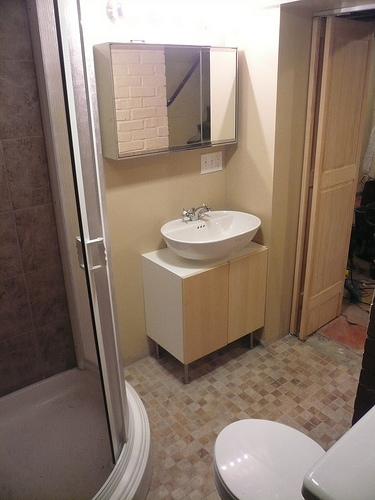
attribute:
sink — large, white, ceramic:
[157, 205, 261, 266]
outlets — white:
[199, 143, 227, 175]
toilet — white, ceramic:
[206, 396, 373, 497]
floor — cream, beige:
[126, 317, 360, 499]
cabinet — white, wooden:
[143, 233, 272, 369]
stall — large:
[3, 0, 159, 497]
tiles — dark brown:
[0, 4, 81, 394]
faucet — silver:
[177, 200, 210, 223]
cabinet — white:
[139, 240, 271, 366]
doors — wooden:
[188, 249, 270, 362]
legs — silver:
[152, 328, 257, 385]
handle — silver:
[179, 200, 214, 226]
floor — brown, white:
[173, 380, 273, 416]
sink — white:
[141, 190, 290, 304]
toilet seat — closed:
[165, 366, 365, 498]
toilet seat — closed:
[210, 364, 349, 496]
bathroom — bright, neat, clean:
[3, 2, 373, 494]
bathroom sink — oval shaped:
[143, 153, 288, 316]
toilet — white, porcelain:
[153, 317, 372, 498]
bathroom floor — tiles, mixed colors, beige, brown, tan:
[188, 340, 370, 413]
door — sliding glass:
[1, 2, 109, 488]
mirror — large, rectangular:
[86, 29, 251, 185]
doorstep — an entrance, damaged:
[286, 254, 373, 369]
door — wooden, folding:
[268, 8, 372, 372]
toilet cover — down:
[182, 357, 347, 498]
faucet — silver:
[168, 186, 236, 231]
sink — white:
[143, 192, 281, 284]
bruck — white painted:
[96, 40, 179, 168]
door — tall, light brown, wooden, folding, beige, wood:
[288, 14, 373, 342]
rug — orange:
[318, 300, 371, 355]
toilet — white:
[214, 402, 371, 498]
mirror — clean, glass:
[163, 43, 210, 149]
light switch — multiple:
[199, 151, 222, 172]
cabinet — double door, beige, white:
[141, 242, 268, 383]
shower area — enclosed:
[2, 0, 155, 497]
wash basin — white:
[161, 209, 261, 264]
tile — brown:
[181, 394, 193, 404]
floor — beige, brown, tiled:
[120, 334, 364, 497]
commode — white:
[208, 418, 324, 498]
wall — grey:
[0, 0, 81, 396]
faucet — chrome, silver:
[181, 203, 212, 222]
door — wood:
[185, 258, 228, 365]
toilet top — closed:
[216, 417, 327, 498]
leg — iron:
[183, 361, 189, 382]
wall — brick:
[109, 45, 169, 155]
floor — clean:
[2, 367, 110, 498]